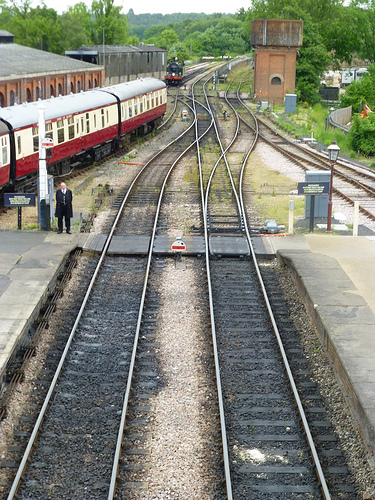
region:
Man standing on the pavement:
[42, 172, 81, 243]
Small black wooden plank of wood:
[213, 456, 350, 495]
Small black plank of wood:
[216, 430, 342, 447]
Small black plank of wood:
[214, 415, 337, 430]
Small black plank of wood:
[213, 401, 327, 413]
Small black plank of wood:
[213, 389, 322, 404]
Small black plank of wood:
[212, 375, 320, 389]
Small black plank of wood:
[2, 439, 156, 455]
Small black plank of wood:
[214, 479, 356, 496]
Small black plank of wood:
[202, 320, 297, 337]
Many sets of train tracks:
[6, 55, 369, 497]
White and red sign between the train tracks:
[171, 235, 186, 258]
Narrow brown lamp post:
[324, 140, 338, 232]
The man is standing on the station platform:
[53, 182, 77, 235]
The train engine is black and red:
[160, 54, 188, 88]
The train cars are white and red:
[0, 74, 169, 199]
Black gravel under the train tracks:
[9, 254, 356, 493]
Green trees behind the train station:
[9, 6, 249, 72]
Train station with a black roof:
[1, 31, 100, 108]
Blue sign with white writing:
[3, 191, 33, 231]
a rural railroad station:
[15, 6, 354, 439]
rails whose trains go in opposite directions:
[45, 240, 319, 482]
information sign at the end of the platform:
[288, 175, 333, 238]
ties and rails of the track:
[200, 259, 279, 331]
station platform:
[286, 245, 369, 312]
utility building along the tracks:
[240, 10, 304, 102]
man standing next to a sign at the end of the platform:
[2, 177, 73, 232]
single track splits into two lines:
[191, 145, 251, 229]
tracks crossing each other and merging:
[165, 83, 260, 203]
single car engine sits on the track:
[160, 49, 187, 85]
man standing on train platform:
[28, 170, 86, 247]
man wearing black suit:
[49, 188, 84, 228]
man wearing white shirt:
[56, 182, 69, 194]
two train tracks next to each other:
[16, 228, 335, 487]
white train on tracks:
[0, 51, 176, 206]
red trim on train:
[4, 99, 179, 189]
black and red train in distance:
[0, 8, 374, 492]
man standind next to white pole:
[30, 97, 81, 231]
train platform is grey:
[1, 217, 76, 385]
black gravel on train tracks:
[182, 269, 317, 459]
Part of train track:
[136, 163, 165, 211]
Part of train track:
[211, 292, 263, 357]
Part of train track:
[64, 389, 103, 449]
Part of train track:
[233, 422, 291, 444]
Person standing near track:
[52, 181, 76, 234]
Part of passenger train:
[104, 79, 170, 137]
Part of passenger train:
[49, 101, 117, 143]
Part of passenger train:
[0, 127, 15, 188]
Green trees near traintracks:
[162, 22, 215, 45]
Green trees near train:
[21, 0, 122, 48]